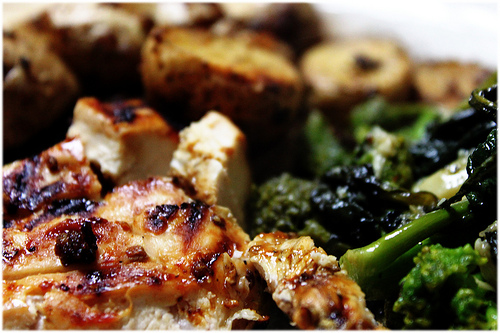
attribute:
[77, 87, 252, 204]
chicken — white meat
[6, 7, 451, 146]
potatoes — in the picture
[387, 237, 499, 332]
broccoli floret — green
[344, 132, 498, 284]
vegetable — green leafy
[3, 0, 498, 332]
meal — in the picture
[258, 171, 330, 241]
broccoli floret — in the picture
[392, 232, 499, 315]
broccoli — in the picture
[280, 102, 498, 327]
spinach — charred, wilted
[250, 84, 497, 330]
veggies — cooked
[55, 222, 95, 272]
chicken —  charred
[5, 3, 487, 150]
potatoes — nicely browned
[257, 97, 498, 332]
green vegetables — pepper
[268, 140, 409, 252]
spinach — in the picture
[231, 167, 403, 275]
brussel sprouts — dark, green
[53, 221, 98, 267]
dark spot — dark 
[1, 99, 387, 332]
chicken — grilled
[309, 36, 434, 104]
potato — in the picture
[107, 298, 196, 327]
interior — white 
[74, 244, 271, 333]
food — cooked